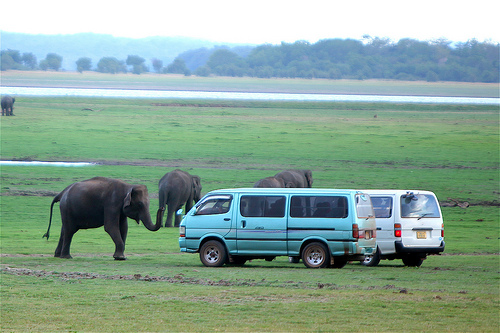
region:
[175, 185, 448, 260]
vans in the field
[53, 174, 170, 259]
elephant in the grass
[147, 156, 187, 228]
elephant in the field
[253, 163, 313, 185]
elephant in the field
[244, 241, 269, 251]
the van is blue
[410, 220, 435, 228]
the van is white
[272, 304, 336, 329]
the grass is short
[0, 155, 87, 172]
water in the grass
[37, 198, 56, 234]
tail of the elephant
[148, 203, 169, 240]
trunk of the elephant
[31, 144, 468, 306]
several elephants in front of two vans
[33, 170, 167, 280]
an elephant standing on grass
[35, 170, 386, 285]
an elephant standing in front of a van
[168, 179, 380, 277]
a light blue van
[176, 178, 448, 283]
two vans beside each other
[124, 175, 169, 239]
the head of an elephant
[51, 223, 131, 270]
the legs of an elephant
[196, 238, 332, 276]
the wheels of a van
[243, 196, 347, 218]
windows on the side of a van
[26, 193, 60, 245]
the tail of an elephant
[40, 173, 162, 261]
elephant walking in grass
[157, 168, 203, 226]
elephant walking in grass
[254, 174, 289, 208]
elephant walking in grass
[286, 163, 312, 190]
elephant walking in grass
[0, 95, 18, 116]
elephant walking in grass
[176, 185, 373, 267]
vehicle parked by elephant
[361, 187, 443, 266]
vehicle parked by elephant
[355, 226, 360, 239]
red light of vehicle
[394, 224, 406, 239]
red light of vehicle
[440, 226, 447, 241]
red light of vehicle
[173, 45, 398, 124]
The trees are in the back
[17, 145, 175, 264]
The elephant has his trunk up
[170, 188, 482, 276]
The vans are parked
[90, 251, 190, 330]
The ground is green and patchy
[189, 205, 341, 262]
The van is blue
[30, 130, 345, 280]
The elephants are standing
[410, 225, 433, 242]
The licence plate is yellow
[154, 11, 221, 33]
The sky is white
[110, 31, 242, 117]
The trees have green leaves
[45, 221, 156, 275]
The elephant has 4 legs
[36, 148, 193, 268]
a group of elephants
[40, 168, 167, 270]
the body of an elephant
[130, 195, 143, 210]
the eye of an elephant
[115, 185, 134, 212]
the ear of an elephant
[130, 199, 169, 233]
the nose of an elephant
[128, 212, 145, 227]
the mouth of an elephant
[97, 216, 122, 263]
the front legs of an elephant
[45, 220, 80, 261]
the back legs of an elephant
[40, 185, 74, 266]
the tail of an elephant